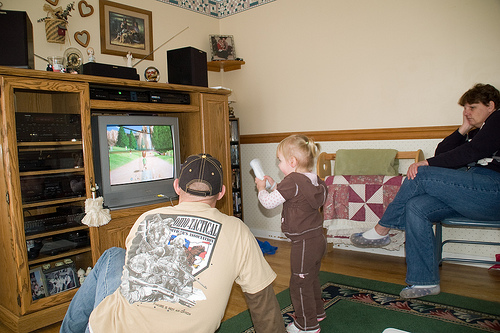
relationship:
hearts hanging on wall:
[73, 31, 92, 49] [19, 1, 220, 95]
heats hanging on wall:
[78, 1, 95, 17] [19, 1, 220, 95]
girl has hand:
[256, 135, 327, 332] [254, 176, 272, 211]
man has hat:
[62, 154, 288, 331] [177, 154, 224, 195]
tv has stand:
[93, 114, 182, 209] [0, 66, 238, 332]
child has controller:
[256, 135, 327, 332] [249, 157, 270, 190]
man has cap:
[62, 154, 288, 331] [177, 154, 224, 195]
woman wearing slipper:
[346, 85, 466, 313] [351, 231, 393, 251]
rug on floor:
[214, 269, 499, 332] [244, 260, 439, 331]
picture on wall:
[99, 2, 155, 61] [226, 15, 474, 198]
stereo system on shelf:
[4, 8, 214, 95] [11, 78, 101, 315]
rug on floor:
[214, 269, 499, 332] [257, 275, 482, 332]